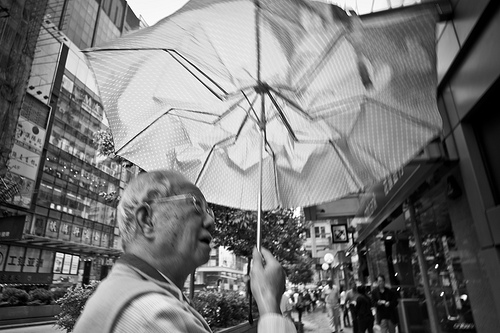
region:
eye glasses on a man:
[160, 186, 213, 220]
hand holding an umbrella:
[243, 228, 285, 315]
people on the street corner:
[298, 271, 399, 331]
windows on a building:
[58, 119, 85, 226]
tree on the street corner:
[219, 206, 307, 332]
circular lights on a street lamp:
[316, 250, 339, 275]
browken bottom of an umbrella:
[195, 44, 319, 164]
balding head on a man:
[110, 178, 174, 249]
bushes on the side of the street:
[13, 278, 100, 328]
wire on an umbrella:
[83, 35, 241, 101]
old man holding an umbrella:
[23, 0, 455, 331]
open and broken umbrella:
[77, 6, 477, 181]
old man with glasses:
[65, 165, 238, 330]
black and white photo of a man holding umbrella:
[2, 2, 474, 327]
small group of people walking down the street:
[311, 245, 406, 327]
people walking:
[345, 273, 402, 328]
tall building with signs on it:
[0, 1, 76, 331]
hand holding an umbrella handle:
[232, 170, 308, 327]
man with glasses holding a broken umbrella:
[0, 2, 453, 327]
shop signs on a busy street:
[316, 221, 363, 273]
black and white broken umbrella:
[69, 8, 444, 216]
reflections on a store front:
[361, 218, 474, 315]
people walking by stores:
[316, 266, 408, 332]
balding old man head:
[106, 171, 223, 271]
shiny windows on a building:
[29, 93, 91, 222]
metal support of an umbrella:
[255, 73, 263, 261]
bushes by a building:
[8, 278, 74, 310]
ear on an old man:
[134, 199, 157, 241]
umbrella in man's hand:
[71, 5, 446, 237]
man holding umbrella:
[54, 141, 304, 330]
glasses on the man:
[83, 187, 224, 213]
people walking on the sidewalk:
[295, 280, 399, 325]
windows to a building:
[29, 154, 114, 238]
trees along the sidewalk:
[227, 205, 309, 290]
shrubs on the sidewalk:
[58, 280, 253, 325]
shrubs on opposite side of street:
[6, 287, 58, 303]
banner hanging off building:
[325, 219, 352, 254]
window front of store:
[418, 208, 480, 329]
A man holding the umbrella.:
[85, 26, 428, 286]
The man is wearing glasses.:
[146, 190, 216, 215]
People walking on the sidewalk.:
[306, 259, 388, 330]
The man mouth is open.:
[191, 231, 216, 256]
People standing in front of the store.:
[319, 279, 397, 323]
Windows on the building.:
[29, 138, 96, 230]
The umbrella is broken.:
[133, 20, 380, 150]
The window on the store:
[396, 221, 467, 323]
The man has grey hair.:
[99, 172, 151, 222]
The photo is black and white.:
[59, 38, 434, 310]